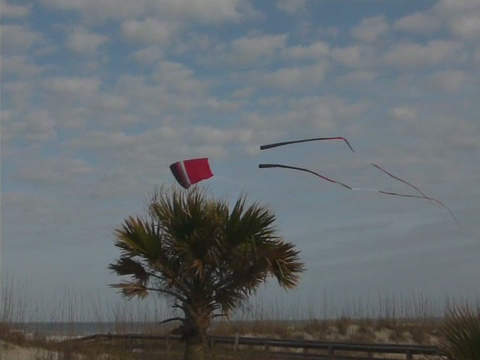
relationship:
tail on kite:
[259, 140, 381, 180] [155, 143, 235, 196]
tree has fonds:
[132, 216, 283, 339] [220, 214, 290, 270]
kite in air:
[155, 143, 235, 196] [121, 137, 288, 228]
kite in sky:
[155, 143, 235, 196] [20, 39, 439, 193]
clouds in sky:
[118, 74, 247, 146] [20, 39, 439, 193]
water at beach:
[34, 311, 129, 332] [19, 288, 479, 347]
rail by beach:
[222, 335, 440, 360] [19, 288, 479, 347]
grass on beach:
[42, 320, 474, 360] [19, 288, 479, 347]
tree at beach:
[132, 216, 283, 339] [19, 288, 479, 347]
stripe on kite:
[179, 162, 190, 185] [155, 143, 235, 196]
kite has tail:
[155, 143, 235, 196] [259, 140, 381, 180]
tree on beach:
[132, 216, 283, 339] [19, 288, 479, 347]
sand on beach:
[9, 341, 56, 359] [19, 288, 479, 347]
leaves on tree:
[144, 233, 180, 282] [132, 216, 283, 339]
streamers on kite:
[314, 147, 443, 225] [155, 143, 235, 196]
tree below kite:
[132, 216, 283, 339] [155, 143, 235, 196]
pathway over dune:
[252, 321, 437, 337] [307, 330, 436, 344]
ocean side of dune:
[47, 299, 449, 323] [307, 330, 436, 344]